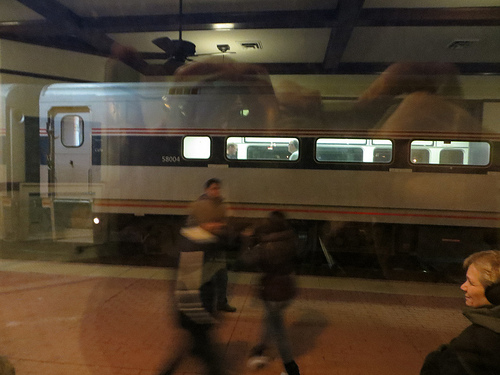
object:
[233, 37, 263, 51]
vent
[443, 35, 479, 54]
vent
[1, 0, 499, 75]
ceiling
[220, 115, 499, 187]
windows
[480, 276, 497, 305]
ear muffs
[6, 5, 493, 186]
window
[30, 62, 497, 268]
train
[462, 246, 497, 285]
hair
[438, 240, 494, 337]
view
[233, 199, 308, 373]
people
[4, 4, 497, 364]
station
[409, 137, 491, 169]
window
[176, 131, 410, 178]
windows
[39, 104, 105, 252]
door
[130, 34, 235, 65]
ceiling fan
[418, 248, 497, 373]
woman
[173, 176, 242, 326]
people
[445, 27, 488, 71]
vent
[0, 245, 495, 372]
sidewalk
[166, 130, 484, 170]
windows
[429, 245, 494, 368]
lady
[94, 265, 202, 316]
brick